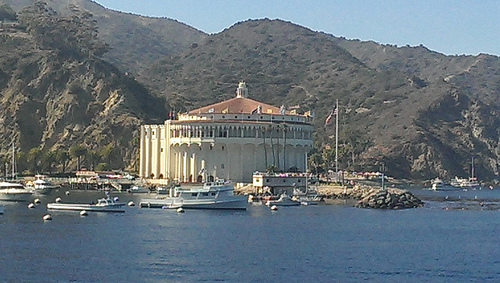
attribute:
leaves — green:
[23, 144, 40, 167]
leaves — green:
[40, 150, 60, 163]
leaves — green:
[51, 146, 73, 166]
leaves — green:
[68, 142, 89, 166]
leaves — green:
[101, 140, 121, 162]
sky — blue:
[173, 5, 494, 90]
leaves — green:
[71, 146, 82, 155]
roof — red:
[198, 84, 277, 120]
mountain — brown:
[148, 1, 495, 215]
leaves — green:
[41, 145, 61, 165]